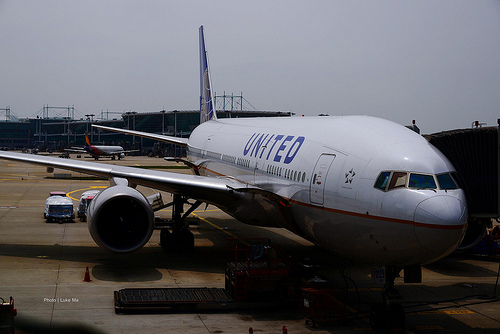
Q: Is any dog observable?
A: No, there are no dogs.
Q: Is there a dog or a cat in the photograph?
A: No, there are no dogs or cats.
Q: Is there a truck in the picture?
A: Yes, there is a truck.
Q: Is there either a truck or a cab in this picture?
A: Yes, there is a truck.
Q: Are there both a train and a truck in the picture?
A: No, there is a truck but no trains.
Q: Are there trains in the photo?
A: No, there are no trains.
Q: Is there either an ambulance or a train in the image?
A: No, there are no trains or ambulances.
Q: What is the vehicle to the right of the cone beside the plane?
A: The vehicle is a truck.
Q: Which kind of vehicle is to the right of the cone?
A: The vehicle is a truck.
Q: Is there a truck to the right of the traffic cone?
A: Yes, there is a truck to the right of the traffic cone.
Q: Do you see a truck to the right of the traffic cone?
A: Yes, there is a truck to the right of the traffic cone.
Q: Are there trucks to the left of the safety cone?
A: No, the truck is to the right of the safety cone.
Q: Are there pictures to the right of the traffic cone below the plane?
A: No, there is a truck to the right of the cone.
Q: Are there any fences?
A: No, there are no fences.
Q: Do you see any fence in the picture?
A: No, there are no fences.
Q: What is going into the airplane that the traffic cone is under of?
A: The tunnel is going into the airplane.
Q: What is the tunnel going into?
A: The tunnel is going into the plane.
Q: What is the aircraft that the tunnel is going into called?
A: The aircraft is an airplane.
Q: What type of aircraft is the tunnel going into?
A: The tunnel is going into the plane.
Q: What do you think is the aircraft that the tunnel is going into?
A: The aircraft is an airplane.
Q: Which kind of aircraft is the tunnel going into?
A: The tunnel is going into the plane.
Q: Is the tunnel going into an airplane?
A: Yes, the tunnel is going into an airplane.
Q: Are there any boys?
A: No, there are no boys.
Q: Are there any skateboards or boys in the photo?
A: No, there are no boys or skateboards.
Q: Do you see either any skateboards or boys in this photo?
A: No, there are no boys or skateboards.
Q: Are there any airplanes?
A: Yes, there is an airplane.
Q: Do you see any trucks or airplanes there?
A: Yes, there is an airplane.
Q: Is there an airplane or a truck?
A: Yes, there is an airplane.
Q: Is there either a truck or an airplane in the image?
A: Yes, there is an airplane.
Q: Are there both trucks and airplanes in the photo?
A: Yes, there are both an airplane and a truck.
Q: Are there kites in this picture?
A: No, there are no kites.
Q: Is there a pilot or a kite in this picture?
A: No, there are no kites or pilots.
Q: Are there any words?
A: Yes, there are words.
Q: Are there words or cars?
A: Yes, there are words.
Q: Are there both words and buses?
A: No, there are words but no buses.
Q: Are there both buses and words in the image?
A: No, there are words but no buses.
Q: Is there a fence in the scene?
A: No, there are no fences.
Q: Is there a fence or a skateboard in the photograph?
A: No, there are no fences or skateboards.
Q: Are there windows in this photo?
A: Yes, there are windows.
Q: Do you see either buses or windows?
A: Yes, there are windows.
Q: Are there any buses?
A: No, there are no buses.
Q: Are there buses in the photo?
A: No, there are no buses.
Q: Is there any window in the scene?
A: Yes, there is a window.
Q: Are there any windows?
A: Yes, there is a window.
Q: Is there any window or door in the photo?
A: Yes, there is a window.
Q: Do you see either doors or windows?
A: Yes, there is a window.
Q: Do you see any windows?
A: Yes, there is a window.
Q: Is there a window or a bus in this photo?
A: Yes, there is a window.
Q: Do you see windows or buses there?
A: Yes, there is a window.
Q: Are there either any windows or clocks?
A: Yes, there is a window.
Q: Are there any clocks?
A: No, there are no clocks.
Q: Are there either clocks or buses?
A: No, there are no clocks or buses.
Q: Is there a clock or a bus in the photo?
A: No, there are no clocks or buses.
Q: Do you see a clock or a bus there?
A: No, there are no clocks or buses.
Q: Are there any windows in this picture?
A: Yes, there is a window.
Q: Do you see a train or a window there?
A: Yes, there is a window.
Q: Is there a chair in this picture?
A: No, there are no chairs.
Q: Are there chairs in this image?
A: No, there are no chairs.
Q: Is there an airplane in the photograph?
A: Yes, there is an airplane.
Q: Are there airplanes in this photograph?
A: Yes, there is an airplane.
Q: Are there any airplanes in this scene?
A: Yes, there is an airplane.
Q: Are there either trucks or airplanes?
A: Yes, there is an airplane.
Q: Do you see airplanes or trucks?
A: Yes, there is an airplane.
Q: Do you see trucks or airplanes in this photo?
A: Yes, there is an airplane.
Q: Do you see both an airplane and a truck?
A: Yes, there are both an airplane and a truck.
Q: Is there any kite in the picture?
A: No, there are no kites.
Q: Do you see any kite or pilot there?
A: No, there are no kites or pilots.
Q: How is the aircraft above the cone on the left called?
A: The aircraft is an airplane.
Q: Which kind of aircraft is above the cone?
A: The aircraft is an airplane.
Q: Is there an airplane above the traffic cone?
A: Yes, there is an airplane above the traffic cone.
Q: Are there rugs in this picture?
A: No, there are no rugs.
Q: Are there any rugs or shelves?
A: No, there are no rugs or shelves.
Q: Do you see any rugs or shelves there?
A: No, there are no rugs or shelves.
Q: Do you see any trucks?
A: Yes, there is a truck.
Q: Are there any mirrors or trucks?
A: Yes, there is a truck.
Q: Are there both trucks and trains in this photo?
A: No, there is a truck but no trains.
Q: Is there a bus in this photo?
A: No, there are no buses.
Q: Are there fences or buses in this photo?
A: No, there are no buses or fences.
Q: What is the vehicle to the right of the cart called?
A: The vehicle is a truck.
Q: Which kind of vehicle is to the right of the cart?
A: The vehicle is a truck.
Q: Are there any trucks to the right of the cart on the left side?
A: Yes, there is a truck to the right of the cart.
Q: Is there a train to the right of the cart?
A: No, there is a truck to the right of the cart.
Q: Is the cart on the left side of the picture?
A: Yes, the cart is on the left of the image.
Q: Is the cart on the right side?
A: No, the cart is on the left of the image.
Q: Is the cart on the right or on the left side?
A: The cart is on the left of the image.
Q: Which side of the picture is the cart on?
A: The cart is on the left of the image.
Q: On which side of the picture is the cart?
A: The cart is on the left of the image.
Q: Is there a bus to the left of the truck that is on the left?
A: No, there is a cart to the left of the truck.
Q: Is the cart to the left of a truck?
A: Yes, the cart is to the left of a truck.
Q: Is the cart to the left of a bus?
A: No, the cart is to the left of a truck.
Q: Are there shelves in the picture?
A: No, there are no shelves.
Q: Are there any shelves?
A: No, there are no shelves.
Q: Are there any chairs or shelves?
A: No, there are no shelves or chairs.